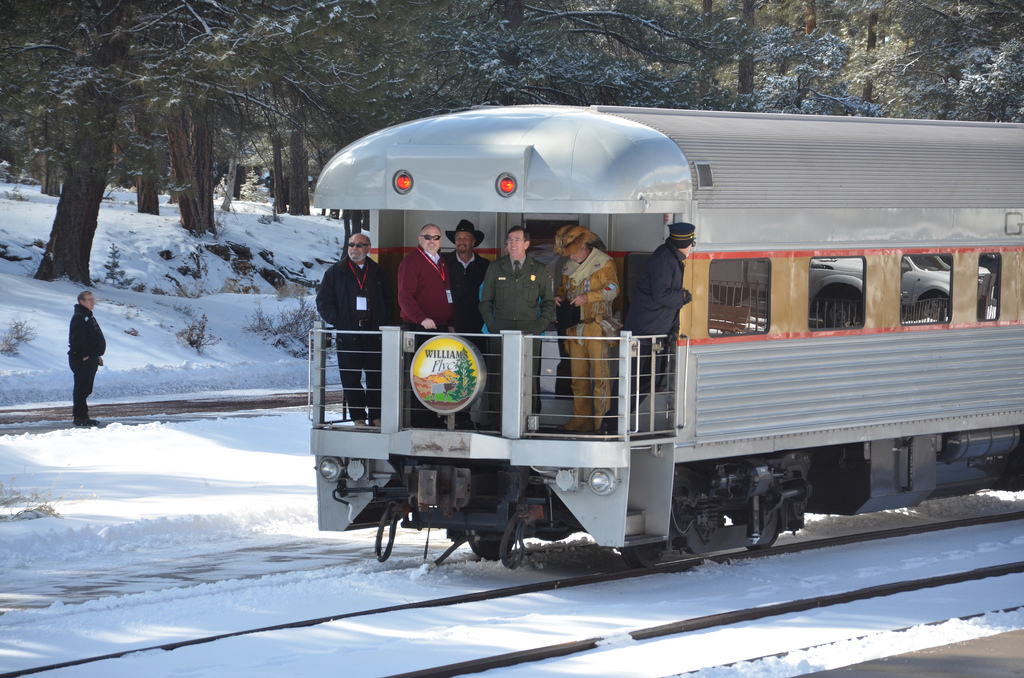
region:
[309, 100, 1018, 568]
passenger train car on the tracks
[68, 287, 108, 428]
man watching a train go by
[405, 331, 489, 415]
round logo on back of train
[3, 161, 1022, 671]
white snow covering the ground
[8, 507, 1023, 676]
train tracks in the snow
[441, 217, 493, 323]
man is wearing a cowboy hat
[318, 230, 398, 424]
man has a lanyard around his neck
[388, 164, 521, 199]
round lights on the back of the train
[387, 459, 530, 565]
the hitch assmbly on a train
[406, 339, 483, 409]
a circular sign with writing on it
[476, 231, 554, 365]
a man in a green uniform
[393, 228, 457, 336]
a man wearing a maroon shirt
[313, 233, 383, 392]
a man dressed in black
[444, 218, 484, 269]
a man wearing a black hat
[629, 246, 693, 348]
a person wearing a grey coat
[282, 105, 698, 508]
people standing on a train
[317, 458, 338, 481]
a circular light with a clear cover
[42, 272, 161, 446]
a man standing on a sidewalk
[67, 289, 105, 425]
a man standing alone in the snow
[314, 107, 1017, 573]
a silver train on a train track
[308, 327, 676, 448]
a metal silver fence at the back of a train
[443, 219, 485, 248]
a black cowboy hat on man's head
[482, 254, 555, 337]
man wearing a khaki jacket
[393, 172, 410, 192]
a red light on the back of a train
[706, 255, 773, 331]
a square window on a train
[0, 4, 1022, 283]
trees covered in snow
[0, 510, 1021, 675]
train track is covered with snow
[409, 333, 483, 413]
a round sign on the fence of a train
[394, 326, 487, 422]
sign on gray train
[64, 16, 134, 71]
green leaves in brown tree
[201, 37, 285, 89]
green leaves in brown tree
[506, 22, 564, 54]
green leaves in brown tree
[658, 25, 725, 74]
green leaves in brown tree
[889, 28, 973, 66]
green leaves in brown tree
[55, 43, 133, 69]
green leaves in brown tree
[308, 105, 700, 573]
people standing on the rear of a train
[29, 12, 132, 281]
the trunk of a tree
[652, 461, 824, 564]
the wheel assembly of a train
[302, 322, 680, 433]
a silver metal railing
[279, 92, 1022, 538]
a silver, brown, and red train car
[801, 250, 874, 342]
a reflection in a pane of glass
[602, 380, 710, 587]
stairs on the side of a train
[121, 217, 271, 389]
snow on a hillside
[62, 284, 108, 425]
a man that is wearing black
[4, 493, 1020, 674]
a snow covered train track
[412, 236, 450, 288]
a red lanyard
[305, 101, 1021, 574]
the back of a gray and red train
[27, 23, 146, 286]
a large tree trunk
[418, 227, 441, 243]
dark black sunglasses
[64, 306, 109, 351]
a man's black coat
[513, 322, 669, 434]
a gray train rail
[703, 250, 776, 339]
a window of a train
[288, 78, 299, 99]
green leaves on the tree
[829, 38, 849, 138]
green leaves on the tree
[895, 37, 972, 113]
green leaves on the tree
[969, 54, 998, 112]
green leaves on the tree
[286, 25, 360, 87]
green leaves on the tree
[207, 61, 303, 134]
green leaves on the tree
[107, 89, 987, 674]
a train on the tracks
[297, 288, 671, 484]
rail on the train